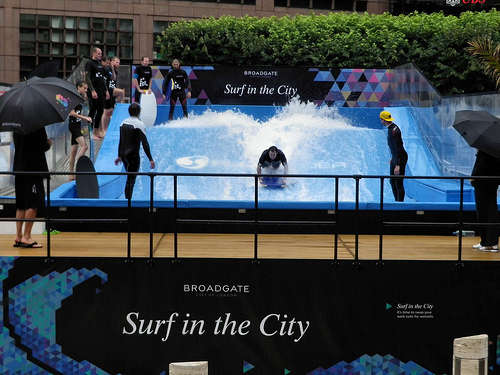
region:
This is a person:
[373, 103, 417, 203]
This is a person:
[241, 137, 306, 212]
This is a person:
[114, 100, 164, 207]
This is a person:
[63, 77, 91, 192]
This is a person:
[8, 87, 67, 259]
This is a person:
[160, 51, 199, 126]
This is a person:
[132, 52, 162, 119]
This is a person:
[103, 55, 123, 140]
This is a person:
[90, 41, 110, 156]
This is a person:
[463, 97, 498, 259]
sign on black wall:
[2, 250, 497, 373]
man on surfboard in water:
[253, 142, 293, 189]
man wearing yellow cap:
[375, 108, 412, 200]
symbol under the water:
[174, 150, 209, 175]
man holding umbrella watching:
[3, 71, 88, 253]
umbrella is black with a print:
[1, 60, 89, 140]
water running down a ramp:
[108, 92, 433, 210]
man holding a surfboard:
[126, 52, 162, 133]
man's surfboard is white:
[134, 85, 162, 130]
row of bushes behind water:
[153, 10, 498, 102]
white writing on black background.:
[112, 315, 305, 336]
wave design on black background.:
[28, 268, 82, 340]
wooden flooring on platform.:
[272, 239, 312, 252]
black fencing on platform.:
[221, 219, 284, 232]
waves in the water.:
[243, 115, 287, 132]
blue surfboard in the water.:
[260, 172, 282, 192]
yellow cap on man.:
[375, 110, 397, 122]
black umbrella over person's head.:
[5, 83, 68, 118]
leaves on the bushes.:
[323, 25, 363, 39]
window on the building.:
[48, 26, 87, 46]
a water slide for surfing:
[111, 73, 433, 200]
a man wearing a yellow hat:
[368, 107, 398, 132]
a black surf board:
[66, 152, 112, 204]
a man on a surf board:
[240, 135, 305, 207]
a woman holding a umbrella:
[0, 58, 80, 150]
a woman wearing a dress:
[12, 71, 54, 253]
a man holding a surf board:
[156, 57, 194, 114]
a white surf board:
[132, 76, 162, 129]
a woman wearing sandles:
[5, 88, 50, 279]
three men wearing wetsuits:
[88, 51, 120, 130]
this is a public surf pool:
[9, 10, 496, 270]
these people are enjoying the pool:
[23, 38, 483, 198]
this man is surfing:
[248, 140, 308, 193]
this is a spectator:
[358, 106, 418, 206]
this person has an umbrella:
[3, 73, 75, 247]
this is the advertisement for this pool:
[114, 296, 320, 346]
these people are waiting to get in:
[70, 47, 196, 143]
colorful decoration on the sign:
[306, 63, 433, 109]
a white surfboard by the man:
[135, 86, 157, 137]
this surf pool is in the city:
[12, 18, 495, 260]